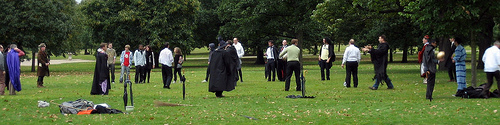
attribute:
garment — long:
[86, 49, 114, 95]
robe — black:
[204, 43, 243, 93]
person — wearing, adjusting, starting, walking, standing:
[6, 35, 500, 97]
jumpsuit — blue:
[450, 45, 472, 89]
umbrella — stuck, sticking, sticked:
[115, 72, 307, 111]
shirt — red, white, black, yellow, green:
[121, 51, 130, 69]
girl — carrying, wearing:
[145, 46, 157, 83]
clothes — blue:
[8, 51, 24, 95]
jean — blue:
[120, 63, 133, 82]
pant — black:
[147, 63, 152, 84]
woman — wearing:
[145, 36, 188, 92]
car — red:
[364, 45, 372, 57]